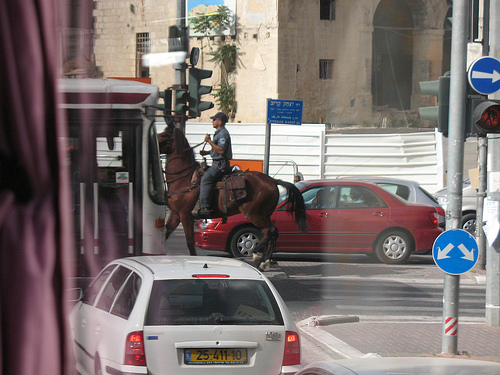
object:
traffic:
[51, 148, 478, 372]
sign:
[429, 228, 480, 277]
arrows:
[433, 242, 475, 262]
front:
[146, 77, 168, 254]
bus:
[21, 74, 165, 264]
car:
[194, 178, 438, 265]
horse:
[159, 125, 310, 258]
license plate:
[183, 349, 249, 365]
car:
[68, 252, 302, 373]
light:
[283, 331, 302, 367]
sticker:
[115, 172, 130, 183]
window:
[93, 127, 133, 255]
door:
[71, 124, 130, 275]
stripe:
[56, 87, 156, 110]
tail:
[271, 174, 308, 230]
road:
[284, 276, 488, 329]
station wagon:
[67, 254, 300, 374]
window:
[154, 279, 262, 325]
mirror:
[63, 287, 83, 301]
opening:
[370, 0, 413, 113]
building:
[90, 1, 460, 126]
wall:
[89, 7, 134, 74]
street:
[297, 261, 470, 336]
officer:
[193, 111, 233, 216]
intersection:
[38, 13, 493, 360]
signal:
[183, 46, 212, 117]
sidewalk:
[339, 317, 471, 371]